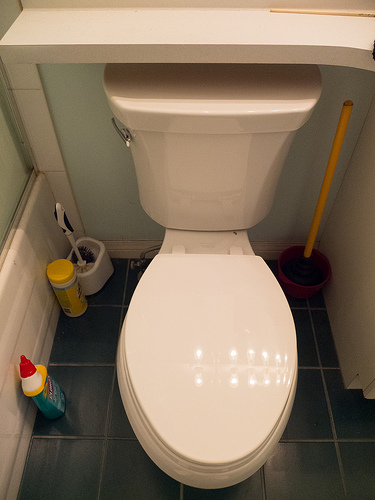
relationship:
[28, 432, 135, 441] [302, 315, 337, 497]
grout line on floor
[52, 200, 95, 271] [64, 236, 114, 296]
brush inside stand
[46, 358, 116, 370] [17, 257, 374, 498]
groutline on floor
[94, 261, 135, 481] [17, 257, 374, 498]
white groutline on floor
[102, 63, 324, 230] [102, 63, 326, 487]
reservoir on toilet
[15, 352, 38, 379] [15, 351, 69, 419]
red cap on bottle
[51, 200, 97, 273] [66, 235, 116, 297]
toilet brush with container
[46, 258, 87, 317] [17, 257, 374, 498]
bottle on floor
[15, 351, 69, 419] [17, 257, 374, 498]
bottle on floor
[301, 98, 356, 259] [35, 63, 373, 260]
handle next to wall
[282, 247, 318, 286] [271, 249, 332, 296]
plunger in bowl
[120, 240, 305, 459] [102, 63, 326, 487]
seat on toilet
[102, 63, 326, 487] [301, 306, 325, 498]
toilet on floor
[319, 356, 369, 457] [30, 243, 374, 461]
blue tile on floor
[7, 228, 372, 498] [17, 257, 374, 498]
blue tile on floor